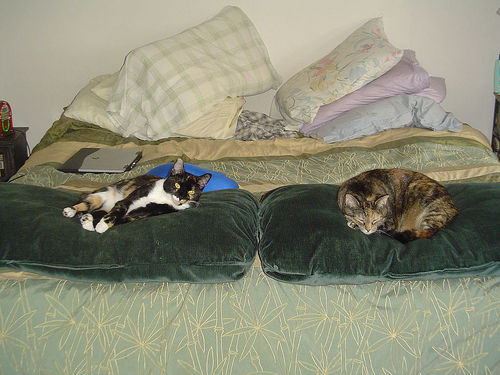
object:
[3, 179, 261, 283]
pillow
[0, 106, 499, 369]
bed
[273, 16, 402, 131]
case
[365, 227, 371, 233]
nose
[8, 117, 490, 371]
blanket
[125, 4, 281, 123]
pillow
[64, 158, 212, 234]
calico cat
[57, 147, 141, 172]
laptop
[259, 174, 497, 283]
pillow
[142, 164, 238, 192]
pillow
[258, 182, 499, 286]
comforter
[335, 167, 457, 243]
cat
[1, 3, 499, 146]
wall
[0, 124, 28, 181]
table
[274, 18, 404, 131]
pillow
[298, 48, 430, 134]
pillow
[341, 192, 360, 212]
ear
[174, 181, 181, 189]
eye